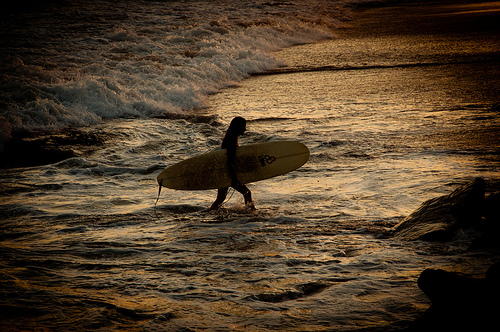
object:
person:
[204, 115, 259, 216]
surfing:
[157, 137, 311, 191]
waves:
[24, 74, 212, 117]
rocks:
[417, 261, 499, 330]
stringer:
[157, 152, 311, 182]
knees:
[240, 189, 256, 199]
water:
[177, 206, 285, 254]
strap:
[153, 179, 237, 221]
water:
[260, 74, 500, 139]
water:
[4, 139, 153, 196]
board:
[248, 139, 311, 176]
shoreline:
[376, 93, 499, 331]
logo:
[256, 152, 276, 166]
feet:
[202, 205, 231, 217]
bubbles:
[45, 106, 149, 111]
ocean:
[3, 1, 499, 117]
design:
[257, 151, 279, 167]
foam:
[124, 61, 204, 113]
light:
[271, 73, 446, 123]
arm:
[221, 136, 245, 191]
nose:
[241, 126, 251, 132]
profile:
[225, 116, 246, 138]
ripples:
[277, 225, 401, 308]